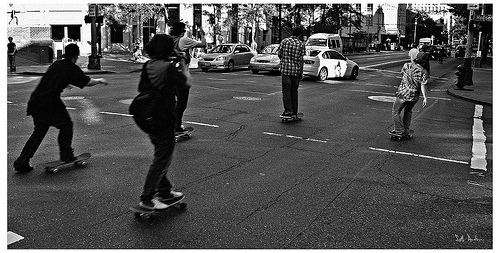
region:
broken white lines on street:
[240, 120, 345, 147]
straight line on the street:
[369, 142, 475, 174]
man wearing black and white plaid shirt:
[264, 32, 320, 74]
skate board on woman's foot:
[118, 184, 228, 221]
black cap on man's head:
[45, 40, 112, 71]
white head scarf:
[399, 46, 439, 71]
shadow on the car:
[305, 40, 372, 89]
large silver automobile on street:
[195, 31, 261, 75]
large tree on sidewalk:
[92, 8, 164, 40]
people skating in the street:
[20, 38, 261, 207]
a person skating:
[269, 24, 309, 122]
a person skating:
[374, 35, 423, 144]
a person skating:
[126, 27, 186, 220]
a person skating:
[155, 7, 209, 142]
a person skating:
[16, 40, 111, 182]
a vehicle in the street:
[291, 40, 363, 86]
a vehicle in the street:
[244, 40, 288, 80]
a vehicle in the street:
[308, 34, 345, 47]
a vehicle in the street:
[201, 40, 255, 75]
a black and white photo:
[4, 0, 488, 245]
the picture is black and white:
[23, 7, 476, 234]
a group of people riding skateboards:
[34, 33, 438, 222]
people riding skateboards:
[21, 20, 459, 215]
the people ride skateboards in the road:
[19, 24, 433, 239]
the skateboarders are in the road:
[21, 23, 438, 250]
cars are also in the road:
[200, 19, 374, 81]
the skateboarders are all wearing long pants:
[16, 26, 438, 233]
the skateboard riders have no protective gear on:
[22, 16, 439, 227]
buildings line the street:
[41, 6, 463, 57]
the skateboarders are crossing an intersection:
[34, 22, 478, 230]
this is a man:
[279, 22, 305, 123]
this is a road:
[229, 124, 354, 243]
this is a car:
[308, 45, 359, 80]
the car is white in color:
[326, 59, 346, 72]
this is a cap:
[61, 45, 77, 53]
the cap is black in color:
[64, 45, 74, 50]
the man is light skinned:
[93, 77, 100, 81]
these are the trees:
[242, 5, 345, 27]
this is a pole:
[413, 15, 418, 42]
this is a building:
[17, 14, 82, 41]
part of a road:
[280, 171, 351, 243]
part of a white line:
[406, 131, 452, 169]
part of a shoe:
[139, 193, 168, 209]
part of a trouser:
[148, 159, 167, 189]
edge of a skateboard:
[154, 187, 187, 212]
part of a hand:
[420, 88, 430, 116]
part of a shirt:
[41, 72, 65, 112]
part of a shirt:
[281, 37, 310, 70]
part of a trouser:
[389, 104, 401, 132]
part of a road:
[298, 161, 339, 221]